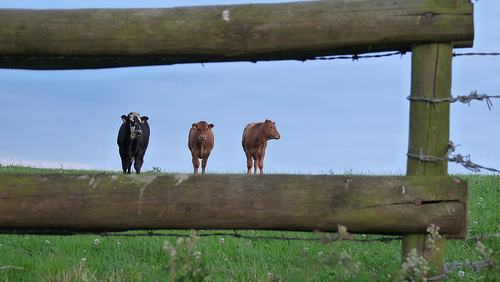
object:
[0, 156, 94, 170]
cloud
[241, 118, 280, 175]
cow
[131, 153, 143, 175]
legs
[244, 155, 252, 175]
legs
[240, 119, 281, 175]
brown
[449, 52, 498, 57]
wire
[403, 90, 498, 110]
wire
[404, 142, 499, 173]
wire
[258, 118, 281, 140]
head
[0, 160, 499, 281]
grass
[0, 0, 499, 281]
fence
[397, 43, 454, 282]
pole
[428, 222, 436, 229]
flower buds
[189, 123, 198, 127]
ear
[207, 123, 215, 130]
ear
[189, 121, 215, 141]
head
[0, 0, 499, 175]
sky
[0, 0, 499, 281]
gate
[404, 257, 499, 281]
barbwire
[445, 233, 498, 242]
barbwire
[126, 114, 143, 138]
face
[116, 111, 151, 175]
cow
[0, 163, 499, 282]
field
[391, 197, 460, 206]
slit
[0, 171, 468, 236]
post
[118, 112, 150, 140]
head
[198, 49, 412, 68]
barbed wire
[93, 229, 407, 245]
barbed wire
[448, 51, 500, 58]
barbed wire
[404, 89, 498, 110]
barbed wire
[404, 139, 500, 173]
barbed wire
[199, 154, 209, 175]
leg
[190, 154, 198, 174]
leg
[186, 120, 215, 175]
cow